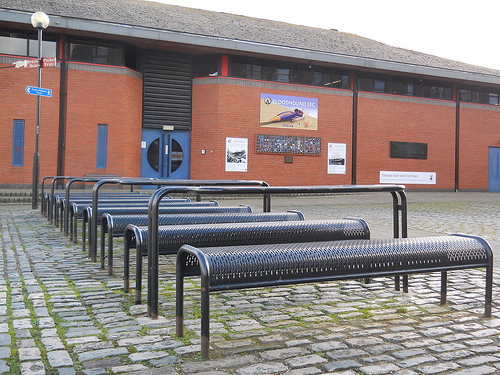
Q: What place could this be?
A: It is a parking lot.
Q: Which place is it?
A: It is a parking lot.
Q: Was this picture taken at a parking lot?
A: Yes, it was taken in a parking lot.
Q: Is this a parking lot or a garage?
A: It is a parking lot.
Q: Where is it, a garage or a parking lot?
A: It is a parking lot.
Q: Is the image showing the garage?
A: No, the picture is showing the parking lot.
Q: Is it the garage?
A: No, it is the parking lot.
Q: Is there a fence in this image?
A: No, there are no fences.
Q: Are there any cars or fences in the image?
A: No, there are no fences or cars.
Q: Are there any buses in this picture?
A: No, there are no buses.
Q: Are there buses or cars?
A: No, there are no buses or cars.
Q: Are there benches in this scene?
A: Yes, there is a bench.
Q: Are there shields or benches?
A: Yes, there is a bench.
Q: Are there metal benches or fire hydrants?
A: Yes, there is a metal bench.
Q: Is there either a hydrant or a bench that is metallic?
A: Yes, the bench is metallic.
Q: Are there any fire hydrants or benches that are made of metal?
A: Yes, the bench is made of metal.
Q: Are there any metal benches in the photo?
A: Yes, there is a metal bench.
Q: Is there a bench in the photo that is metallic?
A: Yes, there is a bench that is metallic.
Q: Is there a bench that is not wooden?
A: Yes, there is a metallic bench.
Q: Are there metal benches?
A: Yes, there is a bench that is made of metal.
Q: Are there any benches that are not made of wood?
A: Yes, there is a bench that is made of metal.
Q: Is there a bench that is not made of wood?
A: Yes, there is a bench that is made of metal.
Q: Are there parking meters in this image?
A: No, there are no parking meters.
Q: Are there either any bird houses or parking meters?
A: No, there are no parking meters or bird houses.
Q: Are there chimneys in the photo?
A: No, there are no chimneys.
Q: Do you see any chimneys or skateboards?
A: No, there are no chimneys or skateboards.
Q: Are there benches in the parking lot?
A: Yes, there are benches in the parking lot.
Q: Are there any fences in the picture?
A: No, there are no fences.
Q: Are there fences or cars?
A: No, there are no fences or cars.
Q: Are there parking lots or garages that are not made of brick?
A: No, there is a parking lot but it is made of brick.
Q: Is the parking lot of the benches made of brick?
A: Yes, the parking lot is made of brick.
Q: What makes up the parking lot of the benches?
A: The parking lot is made of brick.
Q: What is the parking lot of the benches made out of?
A: The parking lot is made of brick.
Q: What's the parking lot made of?
A: The parking lot is made of brick.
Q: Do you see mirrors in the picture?
A: No, there are no mirrors.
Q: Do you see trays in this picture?
A: No, there are no trays.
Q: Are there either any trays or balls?
A: No, there are no trays or balls.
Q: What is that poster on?
A: The poster is on the wall.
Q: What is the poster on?
A: The poster is on the wall.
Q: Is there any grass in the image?
A: Yes, there is grass.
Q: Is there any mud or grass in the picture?
A: Yes, there is grass.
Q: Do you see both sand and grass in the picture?
A: No, there is grass but no sand.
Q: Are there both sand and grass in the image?
A: No, there is grass but no sand.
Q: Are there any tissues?
A: No, there are no tissues.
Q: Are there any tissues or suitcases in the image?
A: No, there are no tissues or suitcases.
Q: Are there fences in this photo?
A: No, there are no fences.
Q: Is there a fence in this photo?
A: No, there are no fences.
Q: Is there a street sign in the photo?
A: Yes, there is a street sign.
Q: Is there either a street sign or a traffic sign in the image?
A: Yes, there is a street sign.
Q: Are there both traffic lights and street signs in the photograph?
A: No, there is a street sign but no traffic lights.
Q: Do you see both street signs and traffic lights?
A: No, there is a street sign but no traffic lights.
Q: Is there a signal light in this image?
A: No, there are no traffic lights.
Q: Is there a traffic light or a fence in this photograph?
A: No, there are no traffic lights or fences.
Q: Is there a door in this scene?
A: Yes, there is a door.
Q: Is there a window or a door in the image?
A: Yes, there is a door.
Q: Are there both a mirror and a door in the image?
A: No, there is a door but no mirrors.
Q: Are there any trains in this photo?
A: No, there are no trains.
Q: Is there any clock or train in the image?
A: No, there are no trains or clocks.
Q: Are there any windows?
A: Yes, there is a window.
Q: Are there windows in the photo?
A: Yes, there is a window.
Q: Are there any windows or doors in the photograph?
A: Yes, there is a window.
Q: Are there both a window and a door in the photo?
A: Yes, there are both a window and a door.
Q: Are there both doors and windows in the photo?
A: Yes, there are both a window and a door.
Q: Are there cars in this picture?
A: No, there are no cars.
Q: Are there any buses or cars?
A: No, there are no cars or buses.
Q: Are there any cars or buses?
A: No, there are no cars or buses.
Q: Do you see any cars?
A: No, there are no cars.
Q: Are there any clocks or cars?
A: No, there are no cars or clocks.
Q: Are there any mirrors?
A: No, there are no mirrors.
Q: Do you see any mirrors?
A: No, there are no mirrors.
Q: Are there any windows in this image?
A: Yes, there are windows.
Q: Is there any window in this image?
A: Yes, there are windows.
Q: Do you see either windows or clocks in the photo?
A: Yes, there are windows.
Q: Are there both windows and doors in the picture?
A: Yes, there are both windows and a door.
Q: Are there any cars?
A: No, there are no cars.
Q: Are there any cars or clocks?
A: No, there are no cars or clocks.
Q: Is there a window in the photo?
A: Yes, there are windows.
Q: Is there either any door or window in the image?
A: Yes, there are windows.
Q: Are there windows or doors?
A: Yes, there are windows.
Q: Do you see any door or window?
A: Yes, there are windows.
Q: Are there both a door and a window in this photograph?
A: Yes, there are both a window and a door.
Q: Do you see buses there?
A: No, there are no buses.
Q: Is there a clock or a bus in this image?
A: No, there are no buses or clocks.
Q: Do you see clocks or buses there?
A: No, there are no buses or clocks.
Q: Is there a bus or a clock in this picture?
A: No, there are no buses or clocks.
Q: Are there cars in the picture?
A: No, there are no cars.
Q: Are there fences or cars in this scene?
A: No, there are no cars or fences.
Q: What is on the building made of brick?
A: The sign is on the building.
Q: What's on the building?
A: The sign is on the building.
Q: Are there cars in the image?
A: No, there are no cars.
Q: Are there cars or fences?
A: No, there are no cars or fences.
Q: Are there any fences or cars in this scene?
A: No, there are no cars or fences.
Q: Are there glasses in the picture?
A: No, there are no glasses.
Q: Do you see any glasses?
A: No, there are no glasses.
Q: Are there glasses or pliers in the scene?
A: No, there are no glasses or pliers.